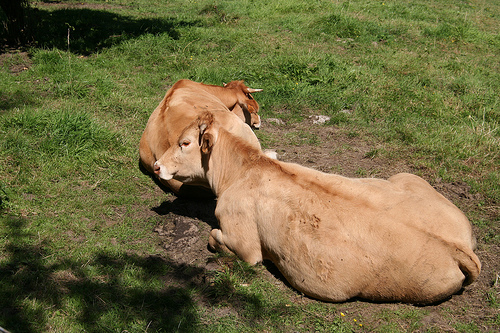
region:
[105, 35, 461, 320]
Two cows laying down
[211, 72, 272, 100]
Horns on a cow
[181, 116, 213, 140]
Horns on a cow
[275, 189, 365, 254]
Light brown fur on a cow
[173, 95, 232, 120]
Light brown fur on a cow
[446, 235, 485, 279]
The tail of a cow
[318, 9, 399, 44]
Patch of thick green grass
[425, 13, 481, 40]
Patch of thick green grass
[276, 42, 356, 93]
Patch of thick green grass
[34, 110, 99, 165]
Patch of thick green grass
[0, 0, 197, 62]
Dark cover of a shadow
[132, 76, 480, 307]
Cows laying on the ground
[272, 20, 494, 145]
Ground with green grass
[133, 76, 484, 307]
Cows of brown color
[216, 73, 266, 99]
Pair of short, thin straight horns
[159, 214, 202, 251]
Piece of dark and bare ground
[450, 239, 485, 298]
Coiled in piece of cow tail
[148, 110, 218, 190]
Brown head of a cow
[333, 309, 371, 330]
Three small yellow flowers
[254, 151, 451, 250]
Long back of a cow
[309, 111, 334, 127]
WHITE PATCH ON GROUND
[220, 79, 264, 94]
HORNS ON COW'S HEAD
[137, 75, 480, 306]
TWO BROWN COWS LAYING DOWN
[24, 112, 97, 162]
PATCH OF OVERGROWN GRASS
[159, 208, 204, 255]
WET MUD ON GROUND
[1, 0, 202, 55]
SHADOW FROM A TREE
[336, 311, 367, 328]
YELLOW FLOWERS ON GROUND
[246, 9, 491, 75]
GREEN GRASSY OVERGROWN FIELD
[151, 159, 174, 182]
TIP OF NOSE IS WHITE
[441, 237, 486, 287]
TAIL IS TUCKED UNDERNEATH COW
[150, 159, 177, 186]
White mouth of a cow.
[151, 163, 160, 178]
Brown nose in the photo.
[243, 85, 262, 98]
Horn in the photo.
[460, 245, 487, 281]
A tail in the photo.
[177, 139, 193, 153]
Brown eyes in the photo.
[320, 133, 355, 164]
A bare ground in the photo.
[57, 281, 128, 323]
Grass in the photo.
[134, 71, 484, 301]
Cattle lying on the ground.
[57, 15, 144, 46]
A shadow in the photo.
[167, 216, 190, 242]
Damp ground in the photo.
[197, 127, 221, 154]
Left ear of cow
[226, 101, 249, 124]
Right ear of cow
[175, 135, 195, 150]
Left eye of cow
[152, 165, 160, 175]
Left nostril of cow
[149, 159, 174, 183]
Nose on the cow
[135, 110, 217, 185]
Head of the cow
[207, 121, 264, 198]
Neck of the cow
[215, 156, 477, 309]
Body of the cow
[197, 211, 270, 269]
Left leg of the cow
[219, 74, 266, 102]
Horns on the cow